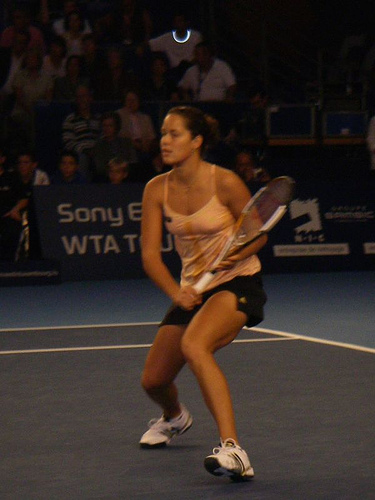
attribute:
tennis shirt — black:
[148, 274, 276, 330]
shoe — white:
[141, 401, 187, 447]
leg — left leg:
[186, 324, 233, 452]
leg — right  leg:
[136, 311, 183, 439]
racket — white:
[200, 171, 304, 273]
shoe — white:
[229, 434, 244, 475]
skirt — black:
[221, 290, 266, 317]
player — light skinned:
[134, 129, 264, 399]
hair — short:
[185, 110, 219, 137]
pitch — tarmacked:
[26, 372, 125, 500]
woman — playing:
[107, 110, 331, 406]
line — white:
[23, 323, 158, 359]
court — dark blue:
[242, 339, 364, 480]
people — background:
[31, 55, 145, 174]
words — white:
[59, 199, 153, 263]